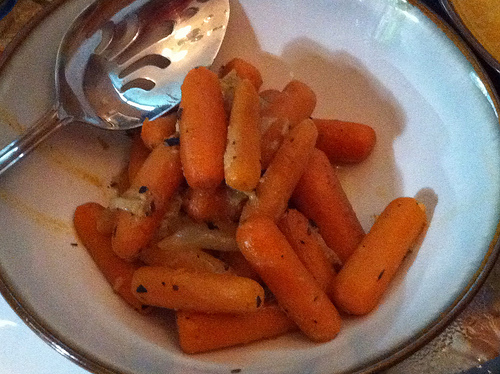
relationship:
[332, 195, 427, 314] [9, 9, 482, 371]
carrot on bowl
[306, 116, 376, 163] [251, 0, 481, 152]
carrot on plate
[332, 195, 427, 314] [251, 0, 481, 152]
carrot on plate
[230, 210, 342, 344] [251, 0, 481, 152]
carrot on plate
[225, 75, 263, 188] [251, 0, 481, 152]
carrot on plate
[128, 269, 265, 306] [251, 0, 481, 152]
carrot on plate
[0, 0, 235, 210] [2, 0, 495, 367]
spoon on plate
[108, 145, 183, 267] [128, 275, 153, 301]
carrot with stuff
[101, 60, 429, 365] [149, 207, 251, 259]
carrot has onions